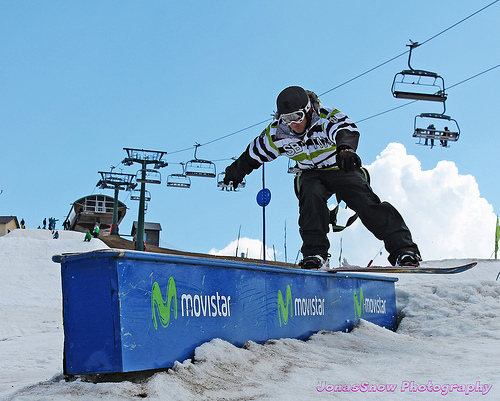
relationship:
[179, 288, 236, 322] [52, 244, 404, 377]
'movistar' logo on ramp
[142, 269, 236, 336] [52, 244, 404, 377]
movistar+logo on ramp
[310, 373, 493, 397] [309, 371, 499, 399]
photographer credit in right hand corner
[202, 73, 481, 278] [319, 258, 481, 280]
dude on snowboard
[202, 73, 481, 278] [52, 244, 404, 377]
dude on ramp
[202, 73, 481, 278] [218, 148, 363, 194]
dude wears gloves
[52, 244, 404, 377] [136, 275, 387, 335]
ramp says 'movistar' 3 times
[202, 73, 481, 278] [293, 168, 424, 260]
dude wears pants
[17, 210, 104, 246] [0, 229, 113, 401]
people walking on slope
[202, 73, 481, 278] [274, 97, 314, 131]
dude wears goggles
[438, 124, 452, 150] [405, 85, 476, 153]
person in chair lift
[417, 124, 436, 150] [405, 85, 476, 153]
person in chair lift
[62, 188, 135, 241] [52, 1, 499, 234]
terminal for ski lift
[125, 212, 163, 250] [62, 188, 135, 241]
office beside terminal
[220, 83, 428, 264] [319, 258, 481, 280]
snowboarder requires snowboard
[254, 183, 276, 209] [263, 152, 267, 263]
sign on pole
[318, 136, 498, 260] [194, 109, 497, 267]
cloud at bottom of sky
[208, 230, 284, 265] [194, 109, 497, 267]
cloud at bottom of sky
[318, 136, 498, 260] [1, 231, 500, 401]
cloud at top of hill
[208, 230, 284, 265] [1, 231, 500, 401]
cloud at top of hill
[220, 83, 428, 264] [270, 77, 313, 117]
snowboarder wears hat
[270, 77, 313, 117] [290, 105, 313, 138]
hat has chinstrap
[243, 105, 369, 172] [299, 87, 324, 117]
jacket has hood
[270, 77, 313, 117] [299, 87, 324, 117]
hat beneath hood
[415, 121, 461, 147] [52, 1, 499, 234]
people ride ski lift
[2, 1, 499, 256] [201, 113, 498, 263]
sky has two prominent clouds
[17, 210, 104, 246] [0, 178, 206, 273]
people at ski resort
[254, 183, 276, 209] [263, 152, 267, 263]
sign bolted to pole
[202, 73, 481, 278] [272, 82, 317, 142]
dude has head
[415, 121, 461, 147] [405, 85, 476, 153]
people sit in chair lift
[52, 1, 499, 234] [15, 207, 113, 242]
ski lift has loading area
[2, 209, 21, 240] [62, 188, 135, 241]
ski lift building beside terminal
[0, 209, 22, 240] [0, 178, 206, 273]
ski lift building belong to ski resort